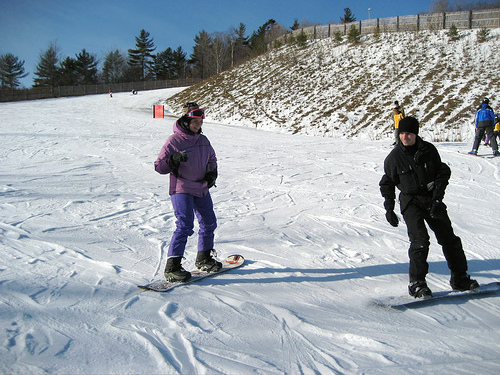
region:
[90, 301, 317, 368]
white snow on the ground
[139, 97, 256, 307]
woman on a snowboard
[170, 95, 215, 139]
woman's goggles are on her head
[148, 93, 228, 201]
woman is wearing a pale purple jacket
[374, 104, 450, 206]
man looking to his right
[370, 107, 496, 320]
man dressed all in black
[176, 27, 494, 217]
rise in ground behind snowboarders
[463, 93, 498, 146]
person wearing a blue and black jacket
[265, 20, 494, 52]
small trees near top of slope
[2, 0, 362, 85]
trees in distance appear dark against the sky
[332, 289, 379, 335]
part of a snow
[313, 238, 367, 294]
part of a shade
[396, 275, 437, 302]
edge of a shoe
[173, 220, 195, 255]
part of a jeans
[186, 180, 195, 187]
part of a jacket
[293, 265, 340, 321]
edge of a shade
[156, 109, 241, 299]
The person is standing on a ski board.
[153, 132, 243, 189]
The girl has on a purple jacket.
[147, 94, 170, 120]
A orange sign is posted on the ground.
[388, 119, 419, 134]
The man has on a black cap.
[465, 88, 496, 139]
The person is wearing a blue jacket.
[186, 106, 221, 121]
The girl has goggle on top of her head.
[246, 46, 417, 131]
Snow and grass on the hill.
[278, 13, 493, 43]
The top of the hill has a fence.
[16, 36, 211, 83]
Trees in the background.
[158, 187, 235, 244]
The woman is wearing purple pants.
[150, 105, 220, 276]
woman is wearing red goggles on her forehead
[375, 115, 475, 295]
man dressed in black clothes has snowboard on feet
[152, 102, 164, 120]
red sign is behind woman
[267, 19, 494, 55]
green vegetation is growing on slope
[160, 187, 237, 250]
woman is wearing blue pants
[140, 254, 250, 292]
woman has snowboard on feet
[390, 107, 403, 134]
man wearing yellow jacket behind man with black clothes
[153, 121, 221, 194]
woman is wearing purple jacket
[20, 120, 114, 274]
white snow on ski path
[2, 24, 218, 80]
green trees are in background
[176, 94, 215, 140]
the head of a person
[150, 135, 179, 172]
the arm of a person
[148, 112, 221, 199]
a lavender coat on the person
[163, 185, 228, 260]
a pair of purple pants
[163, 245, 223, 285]
a pair of black boots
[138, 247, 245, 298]
a white snowboard under the person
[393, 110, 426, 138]
a black stocking cap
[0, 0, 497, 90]
a clear blue sky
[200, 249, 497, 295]
a shadow on the ground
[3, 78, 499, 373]
white snow on the ground